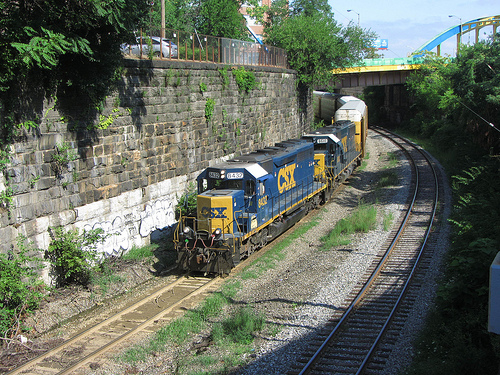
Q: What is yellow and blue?
A: The train.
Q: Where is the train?
A: On the tracks.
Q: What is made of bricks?
A: The wall.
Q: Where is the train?
A: On the tracks.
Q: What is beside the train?
A: A wall.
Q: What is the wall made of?
A: Brick.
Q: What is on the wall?
A: Weeds.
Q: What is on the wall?
A: Graffiti.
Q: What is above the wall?
A: A car.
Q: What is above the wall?
A: A car.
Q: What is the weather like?
A: A sunny day.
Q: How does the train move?
A: An engine.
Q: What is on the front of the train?
A: Lights.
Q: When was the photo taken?
A: Sunny day.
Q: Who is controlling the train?
A: Engineer.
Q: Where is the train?
A: On tracks.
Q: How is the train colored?
A: Blue and yellow.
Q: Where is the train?
A: On tracks.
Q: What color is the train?
A: Blue and yellow.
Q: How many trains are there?
A: One.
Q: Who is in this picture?
A: No one.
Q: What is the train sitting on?
A: Tracks.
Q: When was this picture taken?
A: Daytime.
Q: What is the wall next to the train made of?
A: Bricks.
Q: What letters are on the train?
A: Csx.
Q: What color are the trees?
A: Green.